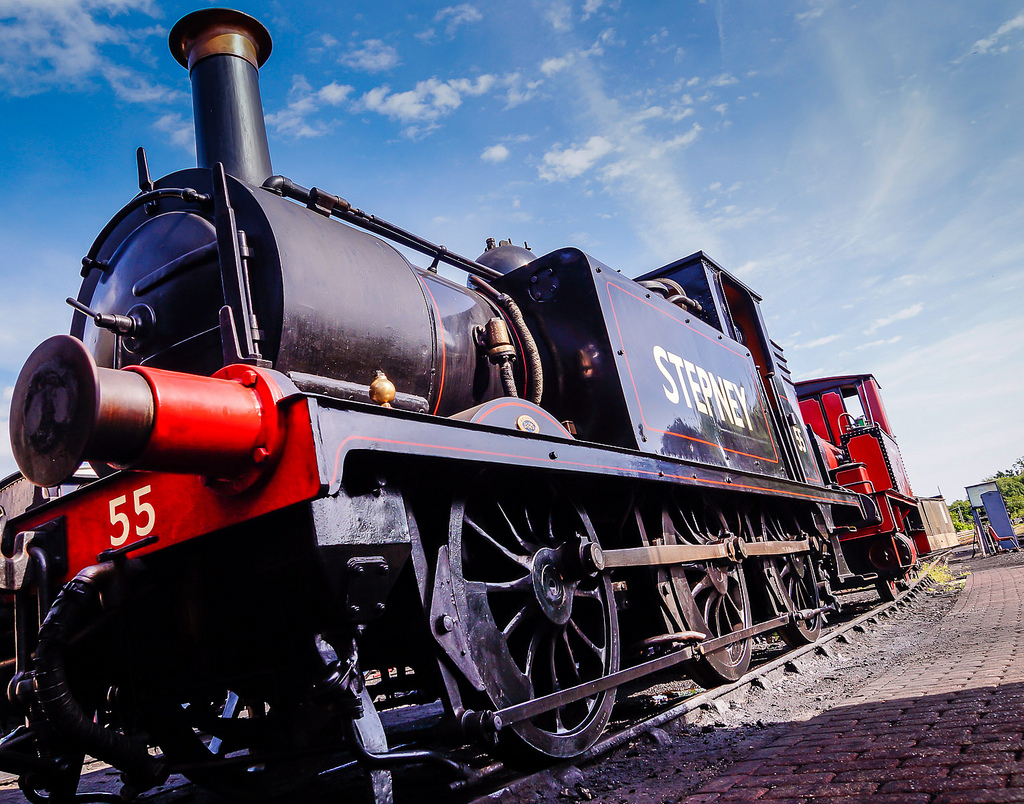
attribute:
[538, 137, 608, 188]
cloud — white, fluffy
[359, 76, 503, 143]
cloud — fluffy, white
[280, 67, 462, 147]
cloud — white, fluffy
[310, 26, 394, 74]
cloud — fluffy, white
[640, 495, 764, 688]
wheel — brown